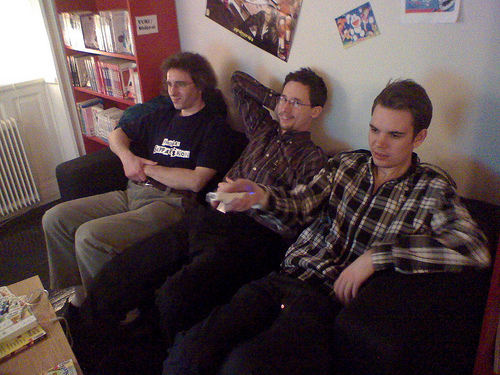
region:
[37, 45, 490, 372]
three men sitting on a couch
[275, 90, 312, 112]
eyeglasses on man's face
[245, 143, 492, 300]
black and white plaid long sleeve shirt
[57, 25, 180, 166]
bookshelf in the corner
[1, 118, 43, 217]
white painted steel radiator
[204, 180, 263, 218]
white Wii remote controller in hand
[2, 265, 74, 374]
light wooden coffee table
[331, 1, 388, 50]
cartoon drawing on wall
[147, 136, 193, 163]
white writing on black tee shirt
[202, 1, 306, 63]
poster hanging on wall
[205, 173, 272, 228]
wii remote is on the hand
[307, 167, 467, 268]
the shirt is cheked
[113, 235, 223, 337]
the pants are black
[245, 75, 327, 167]
the man has glasses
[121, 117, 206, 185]
the shirt is black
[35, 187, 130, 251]
the pants are brown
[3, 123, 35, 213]
the air conditioner is mettalic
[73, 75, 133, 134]
books are on the shelf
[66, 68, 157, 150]
shelf is red in color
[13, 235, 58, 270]
the floor is carpeted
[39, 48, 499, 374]
three people sitting on a couch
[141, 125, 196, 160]
white design on black shirt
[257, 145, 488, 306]
black and white plaid shirt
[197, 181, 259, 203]
white wii remote control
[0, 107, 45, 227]
white radiator on wall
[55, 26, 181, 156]
red bookcase next to window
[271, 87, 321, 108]
pair of eye glasses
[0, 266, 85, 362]
wooden coffee table in front of couch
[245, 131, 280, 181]
white front buttons on plaid shirt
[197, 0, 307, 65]
bottom of poster on wall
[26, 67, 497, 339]
th guys are on the soffa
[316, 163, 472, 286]
the shirt is checked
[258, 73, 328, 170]
the man has glasses on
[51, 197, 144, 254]
the pants are tan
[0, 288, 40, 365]
book is open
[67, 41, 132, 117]
books are on the shelf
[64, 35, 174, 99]
the cardboard is red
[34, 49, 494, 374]
three men on a couch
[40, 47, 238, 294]
guy in a black tee shirt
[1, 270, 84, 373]
small wooden coffee table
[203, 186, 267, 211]
wii remote in a man's hand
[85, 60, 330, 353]
man looking at the camera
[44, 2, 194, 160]
red bookshelf in the corner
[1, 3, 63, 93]
light pouring in throug a window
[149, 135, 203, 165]
words on a black tee shirt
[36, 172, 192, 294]
pair of tan pants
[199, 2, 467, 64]
posters hanging on the wall